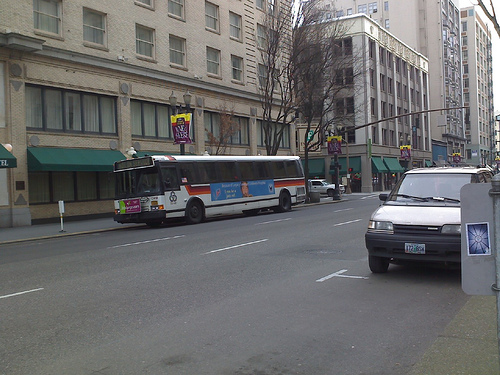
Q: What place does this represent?
A: It represents the road.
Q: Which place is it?
A: It is a road.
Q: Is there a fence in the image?
A: No, there are no fences.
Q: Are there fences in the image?
A: No, there are no fences.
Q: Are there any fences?
A: No, there are no fences.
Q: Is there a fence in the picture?
A: No, there are no fences.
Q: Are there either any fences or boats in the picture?
A: No, there are no fences or boats.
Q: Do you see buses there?
A: Yes, there is a bus.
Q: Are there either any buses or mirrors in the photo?
A: Yes, there is a bus.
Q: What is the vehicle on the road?
A: The vehicle is a bus.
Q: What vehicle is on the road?
A: The vehicle is a bus.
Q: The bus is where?
A: The bus is on the road.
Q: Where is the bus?
A: The bus is on the road.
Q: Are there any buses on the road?
A: Yes, there is a bus on the road.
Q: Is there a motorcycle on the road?
A: No, there is a bus on the road.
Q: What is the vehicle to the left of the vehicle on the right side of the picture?
A: The vehicle is a bus.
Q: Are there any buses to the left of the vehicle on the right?
A: Yes, there is a bus to the left of the vehicle.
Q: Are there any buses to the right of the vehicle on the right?
A: No, the bus is to the left of the vehicle.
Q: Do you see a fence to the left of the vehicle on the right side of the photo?
A: No, there is a bus to the left of the vehicle.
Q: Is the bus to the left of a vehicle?
A: Yes, the bus is to the left of a vehicle.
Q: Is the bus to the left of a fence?
A: No, the bus is to the left of a vehicle.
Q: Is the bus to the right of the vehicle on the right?
A: No, the bus is to the left of the vehicle.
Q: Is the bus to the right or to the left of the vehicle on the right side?
A: The bus is to the left of the vehicle.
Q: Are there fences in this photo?
A: No, there are no fences.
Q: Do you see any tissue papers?
A: No, there are no tissue papers.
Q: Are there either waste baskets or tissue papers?
A: No, there are no tissue papers or waste baskets.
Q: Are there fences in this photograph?
A: No, there are no fences.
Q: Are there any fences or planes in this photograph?
A: No, there are no fences or planes.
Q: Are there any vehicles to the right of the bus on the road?
A: Yes, there is a vehicle to the right of the bus.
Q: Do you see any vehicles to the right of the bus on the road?
A: Yes, there is a vehicle to the right of the bus.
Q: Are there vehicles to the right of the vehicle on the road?
A: Yes, there is a vehicle to the right of the bus.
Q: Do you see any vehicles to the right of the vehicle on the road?
A: Yes, there is a vehicle to the right of the bus.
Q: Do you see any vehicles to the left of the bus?
A: No, the vehicle is to the right of the bus.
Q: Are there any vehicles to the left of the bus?
A: No, the vehicle is to the right of the bus.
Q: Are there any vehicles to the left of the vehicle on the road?
A: No, the vehicle is to the right of the bus.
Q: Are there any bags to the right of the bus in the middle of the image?
A: No, there is a vehicle to the right of the bus.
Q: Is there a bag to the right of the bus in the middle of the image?
A: No, there is a vehicle to the right of the bus.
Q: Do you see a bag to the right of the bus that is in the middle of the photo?
A: No, there is a vehicle to the right of the bus.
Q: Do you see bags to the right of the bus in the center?
A: No, there is a vehicle to the right of the bus.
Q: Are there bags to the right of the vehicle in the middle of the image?
A: No, there is a vehicle to the right of the bus.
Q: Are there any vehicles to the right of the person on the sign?
A: Yes, there is a vehicle to the right of the person.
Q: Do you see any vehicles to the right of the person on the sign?
A: Yes, there is a vehicle to the right of the person.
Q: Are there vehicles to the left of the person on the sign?
A: No, the vehicle is to the right of the person.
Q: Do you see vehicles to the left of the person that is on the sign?
A: No, the vehicle is to the right of the person.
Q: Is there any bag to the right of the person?
A: No, there is a vehicle to the right of the person.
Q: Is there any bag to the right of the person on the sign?
A: No, there is a vehicle to the right of the person.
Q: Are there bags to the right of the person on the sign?
A: No, there is a vehicle to the right of the person.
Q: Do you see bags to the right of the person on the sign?
A: No, there is a vehicle to the right of the person.